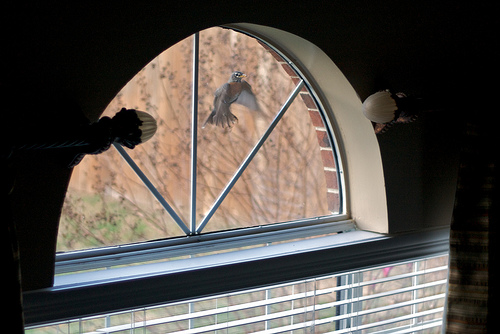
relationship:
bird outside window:
[203, 71, 258, 128] [49, 22, 386, 292]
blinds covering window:
[19, 251, 453, 334] [55, 13, 446, 332]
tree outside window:
[69, 176, 159, 246] [217, 116, 333, 217]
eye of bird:
[234, 73, 238, 76] [198, 67, 272, 131]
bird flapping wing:
[203, 71, 258, 128] [233, 80, 274, 122]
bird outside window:
[202, 56, 279, 138] [49, 22, 386, 292]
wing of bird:
[236, 99, 275, 112] [198, 67, 272, 131]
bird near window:
[203, 71, 258, 128] [49, 22, 386, 292]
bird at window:
[203, 71, 258, 128] [55, 22, 352, 259]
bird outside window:
[203, 71, 258, 128] [55, 22, 352, 259]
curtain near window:
[442, 6, 498, 331] [55, 22, 352, 259]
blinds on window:
[19, 251, 453, 334] [13, 231, 460, 331]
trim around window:
[12, 211, 464, 328] [13, 231, 460, 331]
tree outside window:
[208, 129, 325, 216] [44, 22, 399, 242]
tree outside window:
[69, 176, 159, 246] [79, 283, 455, 332]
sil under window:
[57, 227, 387, 307] [68, 70, 399, 293]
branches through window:
[271, 124, 321, 218] [49, 22, 386, 292]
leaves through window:
[97, 216, 122, 237] [49, 22, 386, 292]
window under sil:
[27, 250, 448, 332] [57, 227, 387, 307]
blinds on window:
[21, 237, 460, 329] [21, 10, 458, 326]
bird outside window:
[203, 71, 258, 128] [73, 27, 438, 297]